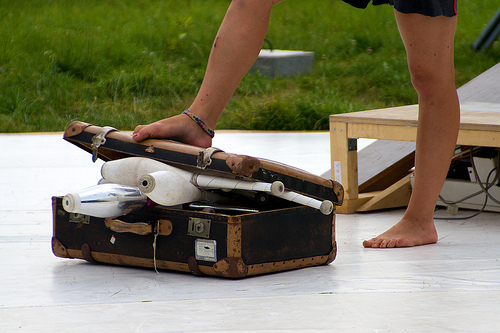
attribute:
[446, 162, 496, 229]
cords — grey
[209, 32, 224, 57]
cut — small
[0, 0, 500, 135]
grass — green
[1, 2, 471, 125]
tall grass — green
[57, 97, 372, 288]
suitcase — old, black and tan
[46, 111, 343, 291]
equipment — electrical, black, white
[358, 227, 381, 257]
toenail — red, painted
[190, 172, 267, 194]
neck — long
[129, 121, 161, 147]
nail — pink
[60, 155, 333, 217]
juggling pins — white, black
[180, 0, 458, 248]
person — stands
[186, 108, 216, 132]
ankle bracelet — blue yellow and orange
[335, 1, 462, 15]
shorts — black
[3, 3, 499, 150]
grass — green